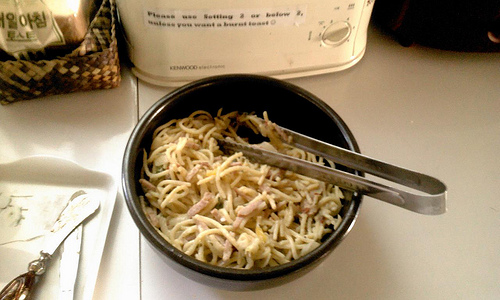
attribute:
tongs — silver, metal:
[216, 106, 450, 219]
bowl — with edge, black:
[121, 70, 369, 282]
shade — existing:
[0, 82, 139, 162]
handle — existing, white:
[323, 21, 351, 46]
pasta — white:
[139, 106, 347, 270]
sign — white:
[142, 1, 308, 32]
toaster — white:
[113, 0, 381, 94]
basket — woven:
[0, 2, 123, 108]